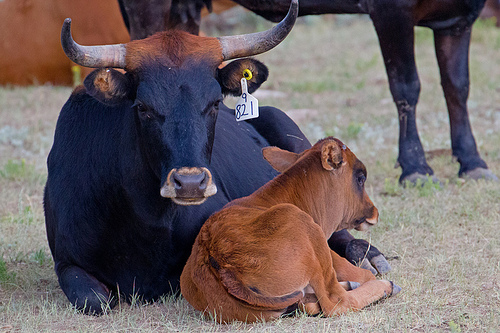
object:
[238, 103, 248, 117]
numbers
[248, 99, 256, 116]
numbers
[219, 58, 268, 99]
ear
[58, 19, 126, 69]
horn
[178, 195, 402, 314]
body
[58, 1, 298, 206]
head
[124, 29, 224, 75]
top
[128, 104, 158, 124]
eyes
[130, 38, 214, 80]
fur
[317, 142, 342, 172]
ear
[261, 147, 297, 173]
ear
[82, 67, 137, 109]
ear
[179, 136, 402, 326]
baby cow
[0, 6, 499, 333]
ground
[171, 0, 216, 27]
utters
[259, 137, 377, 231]
head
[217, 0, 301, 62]
horn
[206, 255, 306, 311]
tail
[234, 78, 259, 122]
tag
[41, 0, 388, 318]
adult cow